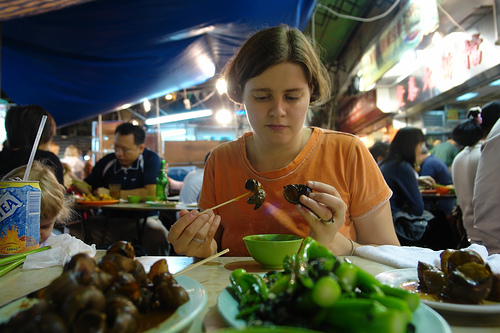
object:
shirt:
[195, 126, 394, 261]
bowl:
[242, 230, 306, 271]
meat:
[244, 176, 269, 211]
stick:
[198, 188, 253, 216]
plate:
[373, 266, 499, 316]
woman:
[165, 24, 404, 260]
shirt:
[376, 157, 435, 241]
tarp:
[0, 0, 318, 135]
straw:
[23, 110, 51, 180]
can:
[0, 175, 43, 258]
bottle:
[156, 156, 172, 203]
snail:
[149, 254, 175, 283]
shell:
[281, 183, 314, 208]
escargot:
[112, 296, 139, 331]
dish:
[1, 270, 210, 332]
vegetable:
[314, 274, 343, 308]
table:
[1, 247, 499, 332]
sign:
[375, 17, 499, 116]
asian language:
[456, 31, 486, 76]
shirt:
[83, 147, 166, 216]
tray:
[417, 187, 440, 196]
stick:
[175, 246, 230, 282]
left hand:
[293, 179, 349, 258]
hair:
[224, 23, 334, 110]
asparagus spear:
[349, 265, 421, 310]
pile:
[1, 241, 192, 332]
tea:
[0, 196, 20, 222]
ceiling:
[0, 0, 379, 133]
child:
[1, 162, 93, 248]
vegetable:
[304, 306, 408, 332]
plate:
[215, 269, 452, 331]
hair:
[380, 126, 428, 174]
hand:
[164, 207, 223, 260]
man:
[79, 120, 173, 256]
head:
[2, 162, 65, 246]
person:
[376, 125, 457, 249]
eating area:
[0, 98, 499, 331]